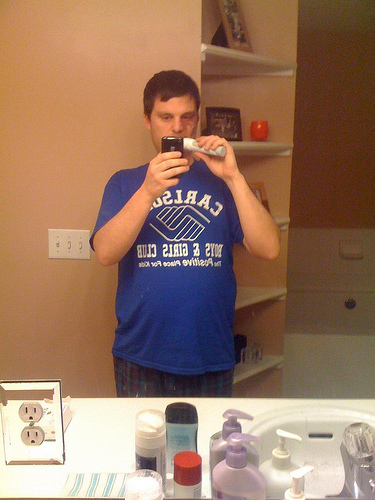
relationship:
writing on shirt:
[135, 240, 231, 274] [86, 153, 246, 374]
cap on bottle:
[170, 448, 202, 486] [169, 445, 203, 489]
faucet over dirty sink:
[321, 421, 374, 499] [242, 405, 373, 495]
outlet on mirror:
[0, 379, 65, 463] [2, 3, 373, 497]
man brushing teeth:
[92, 68, 286, 393] [169, 139, 190, 149]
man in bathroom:
[92, 68, 286, 393] [0, 2, 374, 497]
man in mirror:
[92, 68, 286, 393] [2, 3, 373, 497]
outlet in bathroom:
[0, 379, 65, 463] [0, 2, 374, 497]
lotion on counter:
[200, 400, 273, 497] [1, 394, 373, 496]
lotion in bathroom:
[200, 400, 273, 497] [0, 2, 374, 497]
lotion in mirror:
[200, 400, 273, 497] [2, 3, 373, 497]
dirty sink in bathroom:
[242, 405, 373, 495] [0, 2, 374, 497]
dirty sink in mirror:
[242, 405, 373, 495] [2, 3, 373, 497]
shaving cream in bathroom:
[168, 448, 207, 498] [0, 2, 374, 497]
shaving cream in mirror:
[168, 448, 207, 498] [2, 3, 373, 497]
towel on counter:
[54, 467, 132, 496] [1, 394, 373, 496]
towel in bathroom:
[54, 467, 132, 496] [0, 2, 374, 497]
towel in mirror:
[54, 467, 132, 496] [2, 3, 373, 497]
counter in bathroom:
[1, 394, 373, 496] [0, 2, 374, 497]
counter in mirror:
[1, 394, 373, 496] [2, 3, 373, 497]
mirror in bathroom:
[2, 3, 373, 497] [0, 2, 374, 497]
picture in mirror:
[213, 1, 255, 65] [2, 3, 373, 497]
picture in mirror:
[204, 101, 243, 146] [2, 3, 373, 497]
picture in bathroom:
[213, 1, 255, 65] [0, 2, 374, 497]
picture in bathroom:
[204, 101, 243, 146] [0, 2, 374, 497]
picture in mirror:
[208, 105, 241, 138] [0, 0, 373, 497]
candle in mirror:
[247, 93, 290, 143] [0, 0, 373, 497]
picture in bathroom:
[208, 105, 241, 138] [0, 2, 374, 497]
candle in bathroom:
[247, 93, 290, 143] [0, 2, 374, 497]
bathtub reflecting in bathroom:
[90, 73, 287, 394] [0, 2, 374, 497]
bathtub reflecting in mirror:
[90, 73, 287, 394] [2, 3, 373, 497]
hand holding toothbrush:
[192, 134, 231, 180] [181, 137, 231, 157]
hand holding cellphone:
[143, 152, 227, 221] [157, 126, 240, 181]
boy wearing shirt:
[84, 62, 282, 395] [87, 159, 245, 377]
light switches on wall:
[48, 228, 92, 261] [0, 1, 192, 397]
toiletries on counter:
[117, 395, 320, 499] [1, 394, 373, 496]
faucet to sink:
[276, 407, 345, 487] [246, 408, 373, 498]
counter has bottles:
[1, 394, 373, 496] [124, 392, 316, 499]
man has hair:
[92, 68, 286, 393] [142, 68, 203, 123]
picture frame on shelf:
[202, 103, 246, 146] [197, 129, 293, 157]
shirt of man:
[98, 159, 249, 370] [92, 68, 286, 393]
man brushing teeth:
[92, 68, 286, 393] [162, 132, 198, 151]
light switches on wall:
[44, 225, 92, 258] [5, 1, 302, 380]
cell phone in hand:
[160, 136, 184, 158] [143, 150, 189, 199]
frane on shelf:
[204, 103, 243, 139] [228, 137, 293, 153]